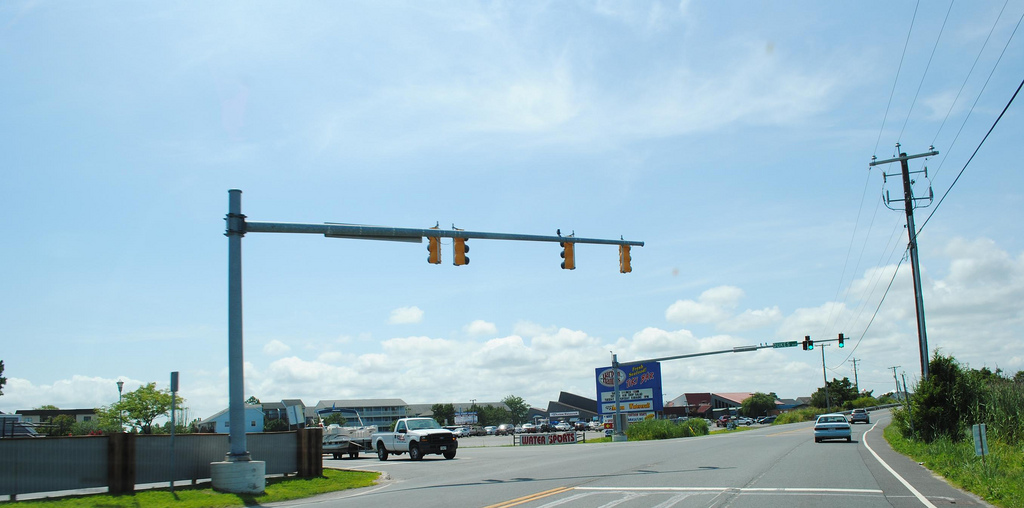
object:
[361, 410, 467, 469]
truck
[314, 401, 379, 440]
boat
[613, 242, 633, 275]
light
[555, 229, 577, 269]
light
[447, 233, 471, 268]
light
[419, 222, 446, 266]
light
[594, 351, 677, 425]
wall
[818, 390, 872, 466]
cars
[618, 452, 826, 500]
road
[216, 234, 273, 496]
pole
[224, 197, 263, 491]
pole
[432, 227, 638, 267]
signal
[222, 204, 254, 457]
post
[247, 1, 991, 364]
wires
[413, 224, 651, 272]
lights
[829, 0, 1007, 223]
wires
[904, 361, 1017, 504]
plants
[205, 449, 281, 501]
pole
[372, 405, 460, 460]
truck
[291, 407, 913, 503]
road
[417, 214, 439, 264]
signal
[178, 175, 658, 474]
pole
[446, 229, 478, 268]
signal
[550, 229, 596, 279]
signal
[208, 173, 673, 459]
pole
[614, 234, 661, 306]
signal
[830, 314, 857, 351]
signal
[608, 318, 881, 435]
pole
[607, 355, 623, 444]
pole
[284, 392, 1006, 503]
street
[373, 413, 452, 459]
truck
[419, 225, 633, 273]
lights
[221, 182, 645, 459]
pole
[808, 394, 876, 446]
cars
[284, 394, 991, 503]
road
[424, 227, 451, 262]
stoplights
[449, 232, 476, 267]
stoplights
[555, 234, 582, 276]
stoplights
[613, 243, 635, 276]
stoplights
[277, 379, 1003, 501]
road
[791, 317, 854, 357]
traffic lights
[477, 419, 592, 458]
rectangular sign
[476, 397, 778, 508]
road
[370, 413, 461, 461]
truck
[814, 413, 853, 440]
car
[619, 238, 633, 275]
light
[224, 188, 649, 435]
pole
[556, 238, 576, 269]
light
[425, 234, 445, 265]
light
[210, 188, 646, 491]
pole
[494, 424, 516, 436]
car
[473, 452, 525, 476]
road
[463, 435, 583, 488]
road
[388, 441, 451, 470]
truck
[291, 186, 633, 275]
light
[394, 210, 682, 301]
traffic lights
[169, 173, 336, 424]
pole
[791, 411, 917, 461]
cars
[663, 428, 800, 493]
road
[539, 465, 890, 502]
line